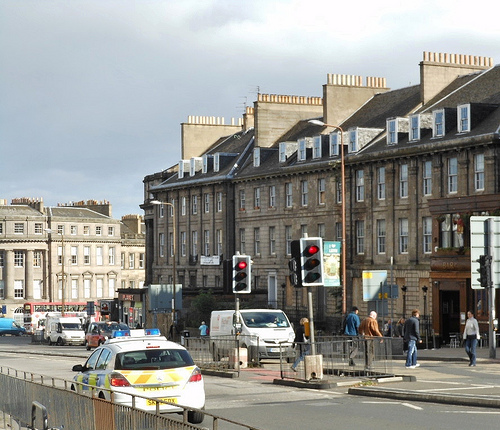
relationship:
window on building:
[315, 180, 327, 209] [138, 42, 498, 360]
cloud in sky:
[1, 3, 500, 196] [1, 12, 483, 196]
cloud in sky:
[1, 3, 324, 196] [1, 12, 483, 196]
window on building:
[253, 187, 261, 209] [138, 42, 498, 360]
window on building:
[267, 185, 276, 207] [138, 42, 498, 360]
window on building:
[283, 182, 293, 205] [138, 42, 498, 360]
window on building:
[295, 173, 315, 212] [138, 42, 498, 360]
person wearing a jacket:
[355, 298, 388, 370] [392, 294, 438, 340]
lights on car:
[108, 318, 161, 336] [68, 322, 216, 425]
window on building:
[186, 197, 223, 213] [132, 93, 499, 354]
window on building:
[295, 173, 315, 212] [237, 93, 350, 348]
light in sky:
[250, 2, 499, 54] [2, 0, 499, 203]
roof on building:
[1, 204, 112, 221] [5, 194, 141, 321]